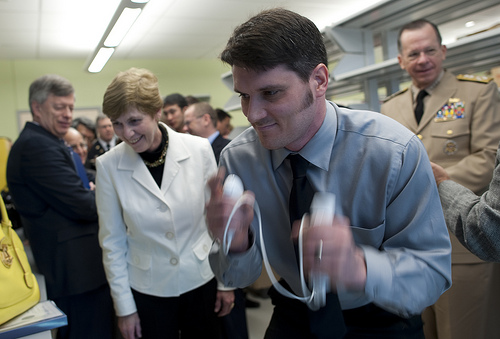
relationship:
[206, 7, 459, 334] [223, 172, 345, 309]
man holding controllers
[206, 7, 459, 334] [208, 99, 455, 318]
man wearing shirt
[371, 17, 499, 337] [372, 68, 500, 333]
man wearing uniform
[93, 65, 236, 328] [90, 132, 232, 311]
woman wearing jacket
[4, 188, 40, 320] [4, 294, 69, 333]
purse on table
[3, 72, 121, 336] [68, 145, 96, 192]
man holding folder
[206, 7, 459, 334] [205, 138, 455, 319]
man shaking arms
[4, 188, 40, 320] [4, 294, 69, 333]
purse on stand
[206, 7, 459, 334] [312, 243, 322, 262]
man wearing ring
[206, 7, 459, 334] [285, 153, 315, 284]
man wearing tie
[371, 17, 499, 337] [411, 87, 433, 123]
man wearing tie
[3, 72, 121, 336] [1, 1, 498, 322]
man in background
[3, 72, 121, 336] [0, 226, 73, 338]
man on stand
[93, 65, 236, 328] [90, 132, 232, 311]
woman has jacket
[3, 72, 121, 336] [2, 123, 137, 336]
man wearing suit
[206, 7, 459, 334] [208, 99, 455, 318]
man holding shirt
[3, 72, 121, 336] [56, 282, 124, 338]
man wears pants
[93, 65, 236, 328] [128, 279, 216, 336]
woman wears skirt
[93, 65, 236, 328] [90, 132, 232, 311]
woman wearing blazer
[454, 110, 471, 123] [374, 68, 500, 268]
pin on jacket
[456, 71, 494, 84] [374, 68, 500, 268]
pin on jacket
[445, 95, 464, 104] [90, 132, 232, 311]
pin on jacket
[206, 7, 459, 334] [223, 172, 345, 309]
man playing controllers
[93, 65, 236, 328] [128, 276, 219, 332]
woman wearing pants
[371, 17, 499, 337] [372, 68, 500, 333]
man in uniform